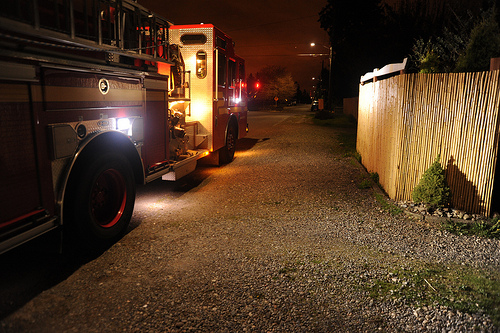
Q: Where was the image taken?
A: It was taken at the road.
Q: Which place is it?
A: It is a road.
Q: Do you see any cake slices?
A: No, there are no cake slices.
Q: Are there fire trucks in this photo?
A: Yes, there is a fire truck.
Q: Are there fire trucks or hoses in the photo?
A: Yes, there is a fire truck.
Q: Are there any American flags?
A: No, there are no American flags.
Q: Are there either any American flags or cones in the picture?
A: No, there are no American flags or cones.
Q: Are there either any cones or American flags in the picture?
A: No, there are no American flags or cones.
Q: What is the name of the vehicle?
A: The vehicle is a fire truck.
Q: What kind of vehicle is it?
A: The vehicle is a fire truck.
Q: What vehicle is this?
A: This is a fire truck.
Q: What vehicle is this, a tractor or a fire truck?
A: This is a fire truck.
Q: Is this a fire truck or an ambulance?
A: This is a fire truck.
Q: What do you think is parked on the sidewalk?
A: The fire truck is parked on the sidewalk.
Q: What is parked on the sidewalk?
A: The fire truck is parked on the sidewalk.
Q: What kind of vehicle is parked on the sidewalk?
A: The vehicle is a fire truck.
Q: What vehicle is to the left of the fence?
A: The vehicle is a fire truck.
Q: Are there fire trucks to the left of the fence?
A: Yes, there is a fire truck to the left of the fence.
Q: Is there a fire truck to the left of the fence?
A: Yes, there is a fire truck to the left of the fence.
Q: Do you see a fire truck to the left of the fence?
A: Yes, there is a fire truck to the left of the fence.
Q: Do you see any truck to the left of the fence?
A: No, there is a fire truck to the left of the fence.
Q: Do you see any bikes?
A: No, there are no bikes.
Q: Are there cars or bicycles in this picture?
A: No, there are no bicycles or cars.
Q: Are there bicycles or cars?
A: No, there are no bicycles or cars.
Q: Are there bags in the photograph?
A: No, there are no bags.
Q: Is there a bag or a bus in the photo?
A: No, there are no bags or buses.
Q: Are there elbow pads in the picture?
A: No, there are no elbow pads.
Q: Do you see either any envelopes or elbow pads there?
A: No, there are no elbow pads or envelopes.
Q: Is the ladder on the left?
A: Yes, the ladder is on the left of the image.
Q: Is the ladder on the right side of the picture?
A: No, the ladder is on the left of the image.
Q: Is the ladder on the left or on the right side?
A: The ladder is on the left of the image.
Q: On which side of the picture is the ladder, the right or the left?
A: The ladder is on the left of the image.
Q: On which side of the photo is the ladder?
A: The ladder is on the left of the image.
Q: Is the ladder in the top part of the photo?
A: Yes, the ladder is in the top of the image.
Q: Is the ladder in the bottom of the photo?
A: No, the ladder is in the top of the image.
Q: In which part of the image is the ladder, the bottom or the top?
A: The ladder is in the top of the image.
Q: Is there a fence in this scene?
A: Yes, there is a fence.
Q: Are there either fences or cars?
A: Yes, there is a fence.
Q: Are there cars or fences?
A: Yes, there is a fence.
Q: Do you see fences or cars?
A: Yes, there is a fence.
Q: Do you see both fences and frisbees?
A: No, there is a fence but no frisbees.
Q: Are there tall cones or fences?
A: Yes, there is a tall fence.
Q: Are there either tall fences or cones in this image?
A: Yes, there is a tall fence.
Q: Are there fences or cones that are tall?
A: Yes, the fence is tall.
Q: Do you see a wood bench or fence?
A: Yes, there is a wood fence.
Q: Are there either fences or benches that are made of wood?
A: Yes, the fence is made of wood.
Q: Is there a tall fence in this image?
A: Yes, there is a tall fence.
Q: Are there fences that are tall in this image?
A: Yes, there is a tall fence.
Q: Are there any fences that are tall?
A: Yes, there is a fence that is tall.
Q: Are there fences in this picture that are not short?
A: Yes, there is a tall fence.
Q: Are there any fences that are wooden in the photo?
A: Yes, there is a wood fence.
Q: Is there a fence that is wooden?
A: Yes, there is a fence that is wooden.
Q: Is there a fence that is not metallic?
A: Yes, there is a wooden fence.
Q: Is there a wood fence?
A: Yes, there is a fence that is made of wood.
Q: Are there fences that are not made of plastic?
A: Yes, there is a fence that is made of wood.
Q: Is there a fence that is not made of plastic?
A: Yes, there is a fence that is made of wood.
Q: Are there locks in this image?
A: No, there are no locks.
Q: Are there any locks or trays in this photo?
A: No, there are no locks or trays.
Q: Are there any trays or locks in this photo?
A: No, there are no locks or trays.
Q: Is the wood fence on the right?
A: Yes, the fence is on the right of the image.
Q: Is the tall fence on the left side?
A: No, the fence is on the right of the image.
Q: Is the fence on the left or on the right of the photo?
A: The fence is on the right of the image.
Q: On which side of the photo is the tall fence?
A: The fence is on the right of the image.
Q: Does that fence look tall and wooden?
A: Yes, the fence is tall and wooden.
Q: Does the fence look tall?
A: Yes, the fence is tall.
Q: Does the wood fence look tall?
A: Yes, the fence is tall.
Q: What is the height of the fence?
A: The fence is tall.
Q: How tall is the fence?
A: The fence is tall.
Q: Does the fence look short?
A: No, the fence is tall.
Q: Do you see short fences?
A: No, there is a fence but it is tall.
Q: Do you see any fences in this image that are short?
A: No, there is a fence but it is tall.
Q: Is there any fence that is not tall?
A: No, there is a fence but it is tall.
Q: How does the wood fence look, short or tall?
A: The fence is tall.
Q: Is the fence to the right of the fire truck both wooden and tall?
A: Yes, the fence is wooden and tall.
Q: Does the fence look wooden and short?
A: No, the fence is wooden but tall.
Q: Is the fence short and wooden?
A: No, the fence is wooden but tall.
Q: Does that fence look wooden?
A: Yes, the fence is wooden.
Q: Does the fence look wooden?
A: Yes, the fence is wooden.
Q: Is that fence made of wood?
A: Yes, the fence is made of wood.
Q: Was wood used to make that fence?
A: Yes, the fence is made of wood.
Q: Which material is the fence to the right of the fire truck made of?
A: The fence is made of wood.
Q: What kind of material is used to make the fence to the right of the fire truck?
A: The fence is made of wood.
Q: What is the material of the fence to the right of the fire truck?
A: The fence is made of wood.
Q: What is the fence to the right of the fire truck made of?
A: The fence is made of wood.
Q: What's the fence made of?
A: The fence is made of wood.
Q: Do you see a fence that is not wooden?
A: No, there is a fence but it is wooden.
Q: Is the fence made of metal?
A: No, the fence is made of wood.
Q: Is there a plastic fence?
A: No, there is a fence but it is made of wood.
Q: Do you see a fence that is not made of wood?
A: No, there is a fence but it is made of wood.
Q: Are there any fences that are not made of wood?
A: No, there is a fence but it is made of wood.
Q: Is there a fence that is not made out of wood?
A: No, there is a fence but it is made of wood.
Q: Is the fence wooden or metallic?
A: The fence is wooden.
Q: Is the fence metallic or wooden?
A: The fence is wooden.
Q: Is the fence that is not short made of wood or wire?
A: The fence is made of wood.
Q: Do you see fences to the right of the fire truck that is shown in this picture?
A: Yes, there is a fence to the right of the fire truck.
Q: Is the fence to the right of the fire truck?
A: Yes, the fence is to the right of the fire truck.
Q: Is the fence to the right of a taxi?
A: No, the fence is to the right of the fire truck.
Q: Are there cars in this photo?
A: No, there are no cars.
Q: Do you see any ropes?
A: No, there are no ropes.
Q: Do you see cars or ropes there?
A: No, there are no ropes or cars.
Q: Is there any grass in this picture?
A: Yes, there is grass.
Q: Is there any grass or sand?
A: Yes, there is grass.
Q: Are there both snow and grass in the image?
A: No, there is grass but no snow.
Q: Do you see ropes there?
A: No, there are no ropes.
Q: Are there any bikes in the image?
A: No, there are no bikes.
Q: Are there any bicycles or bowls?
A: No, there are no bicycles or bowls.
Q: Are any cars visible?
A: No, there are no cars.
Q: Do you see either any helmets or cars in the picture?
A: No, there are no cars or helmets.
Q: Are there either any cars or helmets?
A: No, there are no cars or helmets.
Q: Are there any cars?
A: No, there are no cars.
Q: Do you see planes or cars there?
A: No, there are no cars or planes.